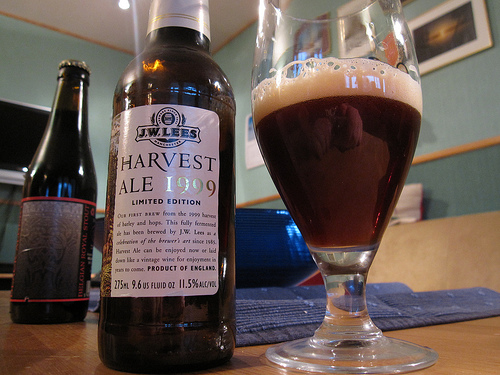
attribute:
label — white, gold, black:
[111, 105, 223, 304]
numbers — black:
[114, 278, 196, 292]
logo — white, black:
[129, 110, 204, 147]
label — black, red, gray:
[10, 193, 98, 303]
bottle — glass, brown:
[101, 2, 243, 367]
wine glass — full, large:
[248, 1, 446, 375]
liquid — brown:
[257, 97, 417, 241]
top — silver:
[60, 59, 96, 77]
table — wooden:
[1, 224, 499, 373]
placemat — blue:
[65, 272, 499, 338]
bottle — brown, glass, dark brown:
[15, 59, 99, 329]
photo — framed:
[406, 1, 492, 69]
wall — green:
[199, 3, 498, 225]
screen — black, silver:
[3, 96, 58, 195]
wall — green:
[3, 16, 138, 233]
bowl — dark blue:
[75, 202, 323, 292]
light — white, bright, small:
[117, 2, 132, 15]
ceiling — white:
[3, 3, 261, 69]